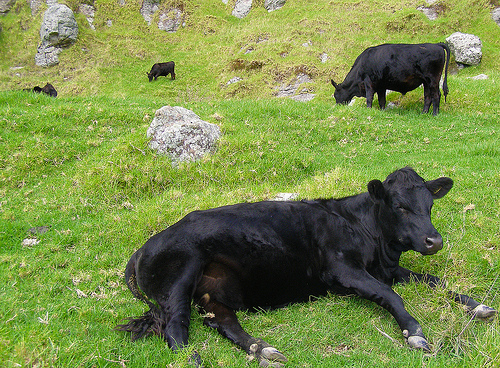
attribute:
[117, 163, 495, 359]
cows — in field, laying in gras, laying on field, on grass, on the ground, black, resting, eating, laying in field, laying on grass, on ground, lying down, in a field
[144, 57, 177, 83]
cow — grazing, in field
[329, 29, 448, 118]
cow — pointing left, in field, black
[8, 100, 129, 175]
grass — bright, yellow, short, green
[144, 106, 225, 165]
rock — big, grey, large, white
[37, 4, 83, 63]
rock — large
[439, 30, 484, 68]
rock — grey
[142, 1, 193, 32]
grey rock — large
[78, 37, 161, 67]
grass — short, yellow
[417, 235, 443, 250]
nose — black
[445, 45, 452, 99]
tail — black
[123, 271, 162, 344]
tail — on ground, on cow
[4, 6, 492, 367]
cows — in field, standing, laying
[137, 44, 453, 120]
cows — standing